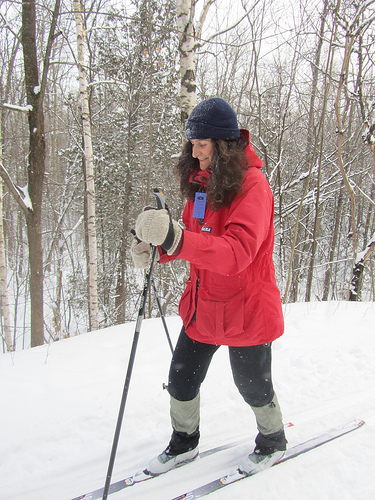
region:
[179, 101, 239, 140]
The hat the woman is wearing.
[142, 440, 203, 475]
The lady's left ski boot.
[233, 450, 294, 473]
The lady's right ski boot.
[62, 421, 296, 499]
The left side ski.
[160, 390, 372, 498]
The right ski.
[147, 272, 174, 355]
The left ski pole.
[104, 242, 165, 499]
The right ski pole.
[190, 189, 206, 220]
The blue tag on the lady's coat.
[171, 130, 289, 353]
The red coat the woman is wearing.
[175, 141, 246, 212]
The woman's brown hair.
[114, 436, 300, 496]
Skies in the snow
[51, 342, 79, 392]
Snow on the ground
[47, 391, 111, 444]
Snow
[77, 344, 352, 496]
Skies going down the ski slope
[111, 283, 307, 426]
Black ski pants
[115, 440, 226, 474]
ski boots attached to skies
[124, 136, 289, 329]
Red ski jacket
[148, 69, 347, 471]
Woman cross country sking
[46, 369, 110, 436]
Lots of snow on the slopes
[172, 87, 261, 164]
Woman wearing a cap while sking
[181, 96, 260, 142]
The woman is wearing a hat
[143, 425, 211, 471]
The woman has shoes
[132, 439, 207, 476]
The woman has white shoes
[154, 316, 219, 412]
The woman is wearing pants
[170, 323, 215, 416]
The woman is wearing black pants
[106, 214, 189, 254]
The woman has gloves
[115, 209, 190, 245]
The woman has white gloves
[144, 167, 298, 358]
The woman is wearing a jacket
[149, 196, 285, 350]
The woman is wearing a red jacket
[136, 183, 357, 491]
The woman is skiing.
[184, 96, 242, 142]
ski cap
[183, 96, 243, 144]
black ski cap dusted with snow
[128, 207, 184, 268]
grey ski mitts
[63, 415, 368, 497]
Set of skis while being worn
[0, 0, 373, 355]
Many bare trees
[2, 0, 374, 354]
many trees dusted with snow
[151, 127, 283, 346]
heavy red winter jacket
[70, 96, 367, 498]
a woman wearing warm winter clothes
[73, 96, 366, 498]
woman skiing down a hill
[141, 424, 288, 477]
Ski boots attached to skis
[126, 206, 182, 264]
a pair of white gloves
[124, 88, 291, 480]
a person wearing white gloves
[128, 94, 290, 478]
a person wearing a hat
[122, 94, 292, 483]
a person wearing a red jacket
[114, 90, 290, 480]
a person wearing a pair of boots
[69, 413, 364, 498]
a pair of skating boards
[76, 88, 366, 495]
a person skating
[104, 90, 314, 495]
a person holding a stick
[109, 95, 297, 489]
a person with long hair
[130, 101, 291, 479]
a person wearing black trousers